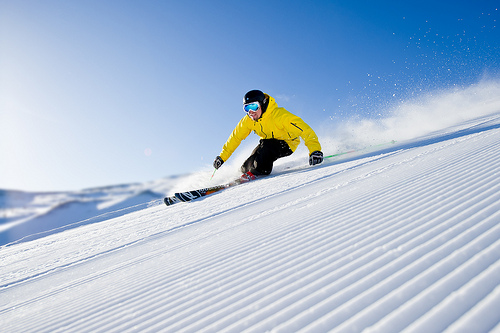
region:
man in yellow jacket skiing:
[157, 88, 322, 210]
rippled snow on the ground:
[2, 113, 497, 330]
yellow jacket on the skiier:
[212, 99, 327, 155]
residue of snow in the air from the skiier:
[164, 71, 494, 194]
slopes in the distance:
[0, 181, 182, 246]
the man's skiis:
[162, 175, 251, 207]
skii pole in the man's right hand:
[207, 164, 219, 189]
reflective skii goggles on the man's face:
[242, 99, 260, 112]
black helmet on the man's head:
[242, 88, 265, 106]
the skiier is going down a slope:
[164, 88, 325, 209]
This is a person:
[203, 67, 339, 199]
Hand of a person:
[278, 110, 337, 174]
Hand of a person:
[186, 116, 250, 169]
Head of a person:
[236, 86, 274, 123]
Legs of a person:
[239, 137, 297, 194]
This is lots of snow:
[131, 262, 302, 329]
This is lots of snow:
[321, 214, 442, 307]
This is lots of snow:
[68, 218, 220, 292]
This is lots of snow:
[24, 161, 119, 233]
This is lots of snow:
[344, 107, 455, 199]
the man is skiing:
[183, 83, 381, 265]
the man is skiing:
[139, 29, 342, 188]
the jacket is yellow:
[200, 94, 343, 164]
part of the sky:
[168, 30, 200, 91]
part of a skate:
[199, 181, 222, 198]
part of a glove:
[304, 138, 324, 175]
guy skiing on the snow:
[0, 0, 498, 325]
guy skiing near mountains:
[7, 72, 327, 256]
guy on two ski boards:
[151, 72, 386, 224]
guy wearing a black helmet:
[156, 60, 363, 220]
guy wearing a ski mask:
[154, 71, 356, 223]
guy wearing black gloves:
[150, 84, 358, 219]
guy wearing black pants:
[148, 75, 332, 213]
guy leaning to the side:
[156, 84, 365, 224]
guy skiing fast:
[35, 62, 499, 264]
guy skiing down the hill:
[45, 47, 495, 291]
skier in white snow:
[161, 81, 322, 215]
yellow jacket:
[211, 99, 329, 150]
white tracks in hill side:
[160, 235, 235, 302]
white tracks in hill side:
[327, 281, 357, 299]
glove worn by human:
[305, 147, 325, 167]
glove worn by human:
[212, 153, 220, 173]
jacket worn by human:
[219, 92, 322, 161]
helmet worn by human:
[241, 87, 268, 115]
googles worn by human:
[242, 99, 261, 113]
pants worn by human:
[240, 133, 292, 175]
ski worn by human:
[174, 178, 245, 203]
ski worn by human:
[162, 196, 179, 206]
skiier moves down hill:
[159, 90, 329, 212]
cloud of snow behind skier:
[324, 70, 496, 160]